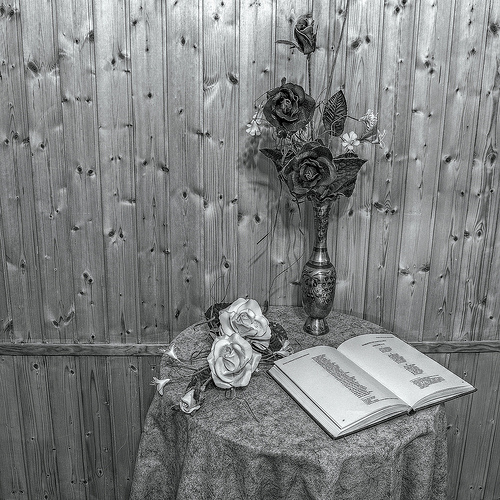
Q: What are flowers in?
A: A vase.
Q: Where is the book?
A: On table.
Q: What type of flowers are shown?
A: Roses.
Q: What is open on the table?
A: A book.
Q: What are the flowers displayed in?
A: A vase.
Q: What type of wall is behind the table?
A: Wood paneled.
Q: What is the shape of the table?
A: Round.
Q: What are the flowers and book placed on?
A: A small table.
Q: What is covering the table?
A: A tablecloth.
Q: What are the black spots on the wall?
A: Knots in the wood.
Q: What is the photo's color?
A: Black and white.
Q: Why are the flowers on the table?
A: For decoration.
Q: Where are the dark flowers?
A: In a vase.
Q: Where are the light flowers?
A: On the table.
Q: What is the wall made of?
A: Wood paneling.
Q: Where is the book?
A: Next to the flowers.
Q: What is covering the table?
A: Tablecloth.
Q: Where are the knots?
A: In the wood.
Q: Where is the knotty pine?
A: Above the table.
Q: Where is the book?
A: On the table.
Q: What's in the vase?
A: Flowers.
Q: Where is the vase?
A: On the table.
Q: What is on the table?
A: A tablecloth.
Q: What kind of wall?
A: Wood.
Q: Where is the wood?
A: On the wall.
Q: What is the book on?
A: A tablecloth.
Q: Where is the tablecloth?
A: On the table.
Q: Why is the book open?
A: To read.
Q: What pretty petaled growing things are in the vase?
A: Flowers.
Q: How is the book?
A: Opened.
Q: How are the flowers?
A: Alive.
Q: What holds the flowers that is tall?
A: Vase.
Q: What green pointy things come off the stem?
A: Leaves.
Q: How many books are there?
A: One.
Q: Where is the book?
A: On the table.